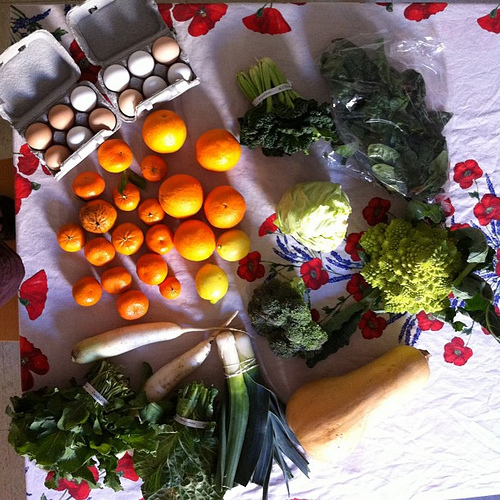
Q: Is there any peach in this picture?
A: No, there are no peaches.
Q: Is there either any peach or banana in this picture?
A: No, there are no peaches or bananas.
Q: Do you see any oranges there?
A: Yes, there are oranges.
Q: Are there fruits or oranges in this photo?
A: Yes, there are oranges.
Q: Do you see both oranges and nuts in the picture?
A: No, there are oranges but no nuts.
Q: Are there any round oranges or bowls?
A: Yes, there are round oranges.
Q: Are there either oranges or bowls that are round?
A: Yes, the oranges are round.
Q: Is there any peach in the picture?
A: No, there are no peaches.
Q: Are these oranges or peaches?
A: These are oranges.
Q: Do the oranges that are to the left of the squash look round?
A: Yes, the oranges are round.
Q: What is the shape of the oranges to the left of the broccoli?
A: The oranges are round.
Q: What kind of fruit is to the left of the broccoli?
A: The fruits are oranges.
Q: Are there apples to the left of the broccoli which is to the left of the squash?
A: No, there are oranges to the left of the broccoli.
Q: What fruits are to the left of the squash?
A: The fruits are oranges.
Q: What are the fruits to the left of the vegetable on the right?
A: The fruits are oranges.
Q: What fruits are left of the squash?
A: The fruits are oranges.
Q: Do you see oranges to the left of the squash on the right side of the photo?
A: Yes, there are oranges to the left of the squash.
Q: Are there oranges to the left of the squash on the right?
A: Yes, there are oranges to the left of the squash.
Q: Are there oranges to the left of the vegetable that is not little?
A: Yes, there are oranges to the left of the squash.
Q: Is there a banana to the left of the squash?
A: No, there are oranges to the left of the squash.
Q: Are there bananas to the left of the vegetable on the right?
A: No, there are oranges to the left of the squash.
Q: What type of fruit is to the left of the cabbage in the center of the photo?
A: The fruits are oranges.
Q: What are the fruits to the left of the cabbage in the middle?
A: The fruits are oranges.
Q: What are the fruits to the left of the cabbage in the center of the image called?
A: The fruits are oranges.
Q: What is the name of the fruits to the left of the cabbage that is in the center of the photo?
A: The fruits are oranges.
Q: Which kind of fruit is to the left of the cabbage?
A: The fruits are oranges.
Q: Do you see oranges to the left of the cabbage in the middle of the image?
A: Yes, there are oranges to the left of the cabbage.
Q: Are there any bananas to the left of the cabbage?
A: No, there are oranges to the left of the cabbage.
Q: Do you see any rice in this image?
A: No, there is no rice.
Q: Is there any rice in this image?
A: No, there is no rice.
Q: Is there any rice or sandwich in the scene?
A: No, there are no rice or sandwiches.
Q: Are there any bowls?
A: No, there are no bowls.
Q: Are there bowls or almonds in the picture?
A: No, there are no bowls or almonds.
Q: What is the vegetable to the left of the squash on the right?
A: The vegetable is a cabbage.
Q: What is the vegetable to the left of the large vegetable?
A: The vegetable is a cabbage.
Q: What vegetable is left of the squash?
A: The vegetable is a cabbage.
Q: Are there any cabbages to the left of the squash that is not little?
A: Yes, there is a cabbage to the left of the squash.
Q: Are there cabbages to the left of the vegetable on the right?
A: Yes, there is a cabbage to the left of the squash.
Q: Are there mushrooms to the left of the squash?
A: No, there is a cabbage to the left of the squash.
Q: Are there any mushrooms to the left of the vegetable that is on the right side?
A: No, there is a cabbage to the left of the squash.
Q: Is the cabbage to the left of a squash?
A: Yes, the cabbage is to the left of a squash.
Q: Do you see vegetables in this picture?
A: Yes, there are vegetables.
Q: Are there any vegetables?
A: Yes, there are vegetables.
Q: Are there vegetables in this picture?
A: Yes, there are vegetables.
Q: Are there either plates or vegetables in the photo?
A: Yes, there are vegetables.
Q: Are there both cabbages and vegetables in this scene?
A: Yes, there are both vegetables and a cabbage.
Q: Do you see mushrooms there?
A: No, there are no mushrooms.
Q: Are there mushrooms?
A: No, there are no mushrooms.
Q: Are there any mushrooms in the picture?
A: No, there are no mushrooms.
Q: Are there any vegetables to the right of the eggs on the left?
A: Yes, there are vegetables to the right of the eggs.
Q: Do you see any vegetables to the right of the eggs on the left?
A: Yes, there are vegetables to the right of the eggs.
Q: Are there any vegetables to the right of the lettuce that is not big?
A: Yes, there are vegetables to the right of the lettuce.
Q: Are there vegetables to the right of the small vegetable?
A: Yes, there are vegetables to the right of the lettuce.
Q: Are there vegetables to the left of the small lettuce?
A: No, the vegetables are to the right of the lettuce.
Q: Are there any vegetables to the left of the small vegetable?
A: No, the vegetables are to the right of the lettuce.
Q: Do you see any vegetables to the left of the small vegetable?
A: No, the vegetables are to the right of the lettuce.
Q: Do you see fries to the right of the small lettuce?
A: No, there are vegetables to the right of the lettuce.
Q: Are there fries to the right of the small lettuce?
A: No, there are vegetables to the right of the lettuce.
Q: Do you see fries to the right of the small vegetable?
A: No, there are vegetables to the right of the lettuce.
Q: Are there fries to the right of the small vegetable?
A: No, there are vegetables to the right of the lettuce.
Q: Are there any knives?
A: No, there are no knives.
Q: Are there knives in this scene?
A: No, there are no knives.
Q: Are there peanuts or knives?
A: No, there are no knives or peanuts.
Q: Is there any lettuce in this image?
A: Yes, there is lettuce.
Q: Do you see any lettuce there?
A: Yes, there is lettuce.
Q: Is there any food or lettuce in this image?
A: Yes, there is lettuce.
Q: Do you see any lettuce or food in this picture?
A: Yes, there is lettuce.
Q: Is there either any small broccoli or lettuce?
A: Yes, there is small lettuce.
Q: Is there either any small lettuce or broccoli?
A: Yes, there is small lettuce.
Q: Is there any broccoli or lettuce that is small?
A: Yes, the lettuce is small.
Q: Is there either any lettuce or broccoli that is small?
A: Yes, the lettuce is small.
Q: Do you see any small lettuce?
A: Yes, there is small lettuce.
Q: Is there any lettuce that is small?
A: Yes, there is lettuce that is small.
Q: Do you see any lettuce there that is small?
A: Yes, there is lettuce that is small.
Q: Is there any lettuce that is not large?
A: Yes, there is small lettuce.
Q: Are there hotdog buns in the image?
A: No, there are no hotdog buns.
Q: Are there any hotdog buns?
A: No, there are no hotdog buns.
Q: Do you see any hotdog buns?
A: No, there are no hotdog buns.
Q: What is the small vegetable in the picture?
A: The vegetable is lettuce.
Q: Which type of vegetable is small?
A: The vegetable is lettuce.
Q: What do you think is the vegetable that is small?
A: The vegetable is lettuce.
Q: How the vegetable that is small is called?
A: The vegetable is lettuce.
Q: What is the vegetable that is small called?
A: The vegetable is lettuce.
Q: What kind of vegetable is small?
A: The vegetable is lettuce.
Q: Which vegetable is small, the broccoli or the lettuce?
A: The lettuce is small.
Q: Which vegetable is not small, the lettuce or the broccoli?
A: The broccoli is not small.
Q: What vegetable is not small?
A: The vegetable is broccoli.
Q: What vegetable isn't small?
A: The vegetable is broccoli.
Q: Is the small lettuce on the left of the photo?
A: Yes, the lettuce is on the left of the image.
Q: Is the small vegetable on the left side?
A: Yes, the lettuce is on the left of the image.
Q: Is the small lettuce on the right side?
A: No, the lettuce is on the left of the image.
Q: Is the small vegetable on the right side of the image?
A: No, the lettuce is on the left of the image.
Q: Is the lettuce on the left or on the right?
A: The lettuce is on the left of the image.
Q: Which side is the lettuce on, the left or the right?
A: The lettuce is on the left of the image.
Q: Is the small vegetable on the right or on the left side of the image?
A: The lettuce is on the left of the image.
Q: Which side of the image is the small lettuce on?
A: The lettuce is on the left of the image.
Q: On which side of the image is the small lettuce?
A: The lettuce is on the left of the image.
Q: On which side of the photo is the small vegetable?
A: The lettuce is on the left of the image.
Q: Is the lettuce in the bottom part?
A: Yes, the lettuce is in the bottom of the image.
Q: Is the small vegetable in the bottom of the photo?
A: Yes, the lettuce is in the bottom of the image.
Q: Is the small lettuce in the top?
A: No, the lettuce is in the bottom of the image.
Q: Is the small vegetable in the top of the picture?
A: No, the lettuce is in the bottom of the image.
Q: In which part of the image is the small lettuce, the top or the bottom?
A: The lettuce is in the bottom of the image.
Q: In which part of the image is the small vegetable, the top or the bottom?
A: The lettuce is in the bottom of the image.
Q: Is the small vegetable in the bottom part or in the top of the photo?
A: The lettuce is in the bottom of the image.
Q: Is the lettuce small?
A: Yes, the lettuce is small.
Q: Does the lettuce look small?
A: Yes, the lettuce is small.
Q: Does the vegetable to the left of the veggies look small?
A: Yes, the lettuce is small.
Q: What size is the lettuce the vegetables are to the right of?
A: The lettuce is small.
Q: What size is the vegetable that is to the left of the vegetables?
A: The lettuce is small.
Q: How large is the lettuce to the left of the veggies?
A: The lettuce is small.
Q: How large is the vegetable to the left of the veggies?
A: The lettuce is small.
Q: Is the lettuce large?
A: No, the lettuce is small.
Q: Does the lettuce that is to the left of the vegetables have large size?
A: No, the lettuce is small.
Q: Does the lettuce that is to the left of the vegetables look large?
A: No, the lettuce is small.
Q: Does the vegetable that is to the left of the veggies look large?
A: No, the lettuce is small.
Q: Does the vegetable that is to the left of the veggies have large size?
A: No, the lettuce is small.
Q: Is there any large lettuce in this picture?
A: No, there is lettuce but it is small.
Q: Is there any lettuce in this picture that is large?
A: No, there is lettuce but it is small.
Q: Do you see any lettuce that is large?
A: No, there is lettuce but it is small.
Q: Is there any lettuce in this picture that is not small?
A: No, there is lettuce but it is small.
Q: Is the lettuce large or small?
A: The lettuce is small.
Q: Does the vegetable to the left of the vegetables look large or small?
A: The lettuce is small.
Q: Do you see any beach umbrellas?
A: No, there are no beach umbrellas.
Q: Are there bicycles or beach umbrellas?
A: No, there are no beach umbrellas or bicycles.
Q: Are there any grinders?
A: No, there are no grinders.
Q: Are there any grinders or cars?
A: No, there are no grinders or cars.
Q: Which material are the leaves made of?
A: The leaves are made of plastic.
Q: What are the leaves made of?
A: The leaves are made of plastic.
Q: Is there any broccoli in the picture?
A: Yes, there is broccoli.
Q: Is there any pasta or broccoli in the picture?
A: Yes, there is broccoli.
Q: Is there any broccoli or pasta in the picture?
A: Yes, there is broccoli.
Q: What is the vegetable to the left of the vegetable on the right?
A: The vegetable is broccoli.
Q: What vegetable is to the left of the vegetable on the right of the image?
A: The vegetable is broccoli.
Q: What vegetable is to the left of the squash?
A: The vegetable is broccoli.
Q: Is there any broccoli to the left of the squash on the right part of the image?
A: Yes, there is broccoli to the left of the squash.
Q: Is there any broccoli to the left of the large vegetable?
A: Yes, there is broccoli to the left of the squash.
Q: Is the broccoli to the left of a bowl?
A: No, the broccoli is to the left of the squash.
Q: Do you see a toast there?
A: No, there are no toasts.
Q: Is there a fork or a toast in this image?
A: No, there are no toasts or forks.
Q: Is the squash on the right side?
A: Yes, the squash is on the right of the image.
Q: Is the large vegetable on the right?
A: Yes, the squash is on the right of the image.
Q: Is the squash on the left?
A: No, the squash is on the right of the image.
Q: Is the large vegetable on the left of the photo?
A: No, the squash is on the right of the image.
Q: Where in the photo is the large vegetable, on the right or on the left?
A: The squash is on the right of the image.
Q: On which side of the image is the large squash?
A: The squash is on the right of the image.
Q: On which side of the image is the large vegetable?
A: The squash is on the right of the image.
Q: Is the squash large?
A: Yes, the squash is large.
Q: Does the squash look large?
A: Yes, the squash is large.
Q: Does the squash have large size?
A: Yes, the squash is large.